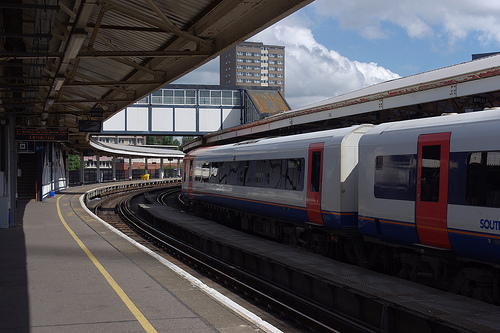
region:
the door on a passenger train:
[186, 153, 193, 197]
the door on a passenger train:
[306, 140, 320, 221]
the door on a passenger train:
[415, 132, 451, 247]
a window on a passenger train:
[181, 158, 186, 174]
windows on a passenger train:
[194, 156, 304, 192]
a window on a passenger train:
[453, 149, 496, 211]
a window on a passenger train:
[377, 156, 414, 203]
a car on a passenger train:
[178, 125, 355, 236]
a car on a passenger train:
[360, 100, 499, 253]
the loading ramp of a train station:
[6, 136, 266, 331]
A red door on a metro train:
[410, 129, 459, 253]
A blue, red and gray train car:
[350, 107, 499, 263]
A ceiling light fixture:
[59, 28, 89, 62]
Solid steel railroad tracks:
[94, 181, 392, 331]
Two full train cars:
[177, 105, 498, 306]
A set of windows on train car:
[191, 156, 305, 193]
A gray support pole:
[127, 155, 133, 180]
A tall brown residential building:
[217, 37, 286, 101]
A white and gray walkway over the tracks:
[90, 79, 248, 137]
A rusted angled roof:
[240, 83, 293, 115]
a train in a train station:
[11, 56, 476, 313]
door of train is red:
[410, 126, 454, 253]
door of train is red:
[298, 135, 328, 227]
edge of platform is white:
[89, 200, 167, 257]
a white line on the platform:
[95, 257, 142, 317]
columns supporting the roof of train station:
[69, 140, 182, 184]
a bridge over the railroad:
[81, 80, 288, 141]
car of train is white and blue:
[170, 120, 366, 227]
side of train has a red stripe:
[174, 183, 364, 220]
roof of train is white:
[181, 101, 496, 154]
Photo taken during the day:
[12, 6, 492, 331]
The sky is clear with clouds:
[268, 10, 480, 110]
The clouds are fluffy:
[269, 4, 478, 99]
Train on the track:
[157, 125, 497, 293]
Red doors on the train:
[181, 138, 457, 248]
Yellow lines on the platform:
[45, 188, 149, 327]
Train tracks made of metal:
[137, 228, 324, 325]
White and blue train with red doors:
[172, 133, 493, 265]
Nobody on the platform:
[39, 142, 209, 327]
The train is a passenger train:
[167, 131, 490, 279]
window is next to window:
[149, 87, 164, 105]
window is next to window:
[163, 88, 175, 105]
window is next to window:
[173, 90, 184, 106]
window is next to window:
[184, 86, 195, 102]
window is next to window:
[198, 88, 210, 104]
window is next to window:
[210, 90, 220, 106]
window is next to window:
[222, 88, 232, 105]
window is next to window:
[232, 91, 240, 107]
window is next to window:
[237, 77, 243, 83]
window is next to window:
[235, 71, 244, 77]